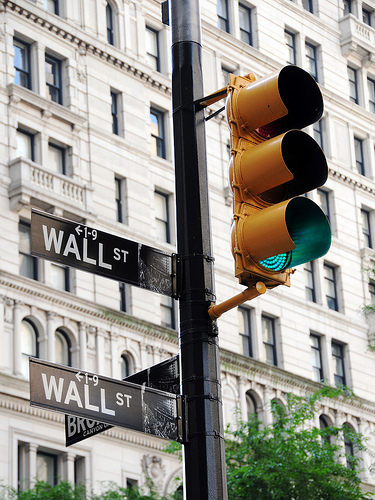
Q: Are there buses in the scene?
A: No, there are no buses.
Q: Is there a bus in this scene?
A: No, there are no buses.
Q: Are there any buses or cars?
A: No, there are no buses or cars.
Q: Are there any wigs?
A: No, there are no wigs.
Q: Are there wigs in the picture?
A: No, there are no wigs.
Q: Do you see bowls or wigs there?
A: No, there are no wigs or bowls.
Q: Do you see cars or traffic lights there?
A: Yes, there is a traffic light.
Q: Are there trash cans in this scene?
A: No, there are no trash cans.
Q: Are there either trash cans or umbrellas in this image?
A: No, there are no trash cans or umbrellas.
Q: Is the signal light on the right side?
A: Yes, the signal light is on the right of the image.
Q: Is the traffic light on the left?
A: No, the traffic light is on the right of the image.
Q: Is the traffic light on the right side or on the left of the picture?
A: The traffic light is on the right of the image.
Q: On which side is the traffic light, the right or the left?
A: The traffic light is on the right of the image.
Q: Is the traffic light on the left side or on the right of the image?
A: The traffic light is on the right of the image.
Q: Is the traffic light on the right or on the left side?
A: The traffic light is on the right of the image.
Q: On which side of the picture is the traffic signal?
A: The traffic signal is on the right of the image.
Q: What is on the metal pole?
A: The traffic light is on the pole.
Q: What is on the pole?
A: The traffic light is on the pole.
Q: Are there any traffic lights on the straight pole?
A: Yes, there is a traffic light on the pole.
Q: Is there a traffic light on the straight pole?
A: Yes, there is a traffic light on the pole.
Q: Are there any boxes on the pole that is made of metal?
A: No, there is a traffic light on the pole.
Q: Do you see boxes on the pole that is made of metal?
A: No, there is a traffic light on the pole.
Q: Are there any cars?
A: No, there are no cars.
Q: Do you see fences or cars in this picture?
A: No, there are no cars or fences.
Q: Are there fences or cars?
A: No, there are no cars or fences.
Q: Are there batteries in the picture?
A: No, there are no batteries.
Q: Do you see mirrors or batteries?
A: No, there are no batteries or mirrors.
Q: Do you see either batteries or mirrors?
A: No, there are no batteries or mirrors.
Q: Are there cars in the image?
A: No, there are no cars.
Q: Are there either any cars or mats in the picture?
A: No, there are no cars or mats.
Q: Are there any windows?
A: Yes, there is a window.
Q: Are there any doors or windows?
A: Yes, there is a window.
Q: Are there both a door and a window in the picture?
A: No, there is a window but no doors.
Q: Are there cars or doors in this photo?
A: No, there are no cars or doors.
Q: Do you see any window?
A: Yes, there is a window.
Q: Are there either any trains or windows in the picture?
A: Yes, there is a window.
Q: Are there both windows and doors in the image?
A: No, there is a window but no doors.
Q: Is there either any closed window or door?
A: Yes, there is a closed window.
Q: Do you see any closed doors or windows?
A: Yes, there is a closed window.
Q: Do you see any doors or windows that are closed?
A: Yes, the window is closed.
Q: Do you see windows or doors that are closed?
A: Yes, the window is closed.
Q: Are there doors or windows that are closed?
A: Yes, the window is closed.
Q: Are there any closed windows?
A: Yes, there is a closed window.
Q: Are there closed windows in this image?
A: Yes, there is a closed window.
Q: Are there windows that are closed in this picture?
A: Yes, there is a closed window.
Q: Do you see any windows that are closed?
A: Yes, there is a closed window.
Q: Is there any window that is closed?
A: Yes, there is a window that is closed.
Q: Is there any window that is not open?
A: Yes, there is an closed window.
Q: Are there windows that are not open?
A: Yes, there is an closed window.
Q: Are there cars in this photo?
A: No, there are no cars.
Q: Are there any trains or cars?
A: No, there are no cars or trains.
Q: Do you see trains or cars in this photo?
A: No, there are no cars or trains.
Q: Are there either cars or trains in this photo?
A: No, there are no cars or trains.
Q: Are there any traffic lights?
A: Yes, there is a traffic light.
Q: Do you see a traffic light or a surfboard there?
A: Yes, there is a traffic light.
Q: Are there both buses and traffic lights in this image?
A: No, there is a traffic light but no buses.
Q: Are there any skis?
A: No, there are no skis.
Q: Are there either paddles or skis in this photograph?
A: No, there are no skis or paddles.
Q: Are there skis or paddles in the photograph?
A: No, there are no skis or paddles.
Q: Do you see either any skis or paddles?
A: No, there are no skis or paddles.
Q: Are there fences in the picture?
A: No, there are no fences.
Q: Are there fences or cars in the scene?
A: No, there are no fences or cars.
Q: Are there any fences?
A: No, there are no fences.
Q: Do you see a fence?
A: No, there are no fences.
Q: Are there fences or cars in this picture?
A: No, there are no fences or cars.